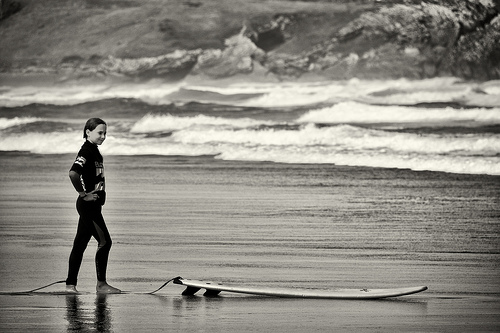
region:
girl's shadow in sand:
[36, 280, 138, 332]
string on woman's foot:
[5, 258, 72, 296]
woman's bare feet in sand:
[52, 275, 100, 297]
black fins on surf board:
[180, 281, 257, 296]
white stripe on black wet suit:
[60, 150, 96, 166]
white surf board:
[166, 265, 461, 310]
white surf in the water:
[300, 93, 405, 123]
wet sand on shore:
[162, 163, 327, 264]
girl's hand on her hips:
[58, 170, 124, 206]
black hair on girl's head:
[70, 109, 108, 144]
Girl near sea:
[49, 111, 142, 304]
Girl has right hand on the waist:
[59, 117, 138, 313]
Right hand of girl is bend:
[56, 109, 137, 311]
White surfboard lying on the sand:
[163, 261, 439, 309]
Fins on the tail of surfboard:
[176, 285, 222, 306]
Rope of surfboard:
[0, 265, 189, 302]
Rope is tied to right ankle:
[5, 269, 187, 308]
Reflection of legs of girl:
[53, 291, 128, 329]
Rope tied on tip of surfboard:
[139, 271, 182, 301]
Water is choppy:
[6, 11, 498, 141]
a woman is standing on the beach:
[50, 111, 125, 303]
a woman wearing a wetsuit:
[61, 116, 112, 294]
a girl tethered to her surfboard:
[6, 116, 187, 306]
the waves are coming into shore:
[0, 65, 495, 190]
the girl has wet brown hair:
[75, 115, 105, 141]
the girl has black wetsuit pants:
[65, 116, 121, 286]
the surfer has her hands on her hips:
[65, 117, 110, 283]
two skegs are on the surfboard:
[176, 271, 221, 301]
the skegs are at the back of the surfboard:
[170, 275, 228, 302]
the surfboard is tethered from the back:
[143, 272, 185, 301]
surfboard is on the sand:
[176, 265, 490, 312]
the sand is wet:
[196, 207, 331, 276]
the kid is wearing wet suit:
[62, 118, 152, 308]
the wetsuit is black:
[67, 151, 144, 307]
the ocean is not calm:
[163, 72, 454, 169]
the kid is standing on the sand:
[61, 108, 144, 320]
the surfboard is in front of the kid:
[157, 230, 435, 320]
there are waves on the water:
[138, 83, 413, 168]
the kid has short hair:
[56, 100, 112, 142]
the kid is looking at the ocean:
[73, 109, 382, 186]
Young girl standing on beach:
[64, 115, 121, 291]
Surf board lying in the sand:
[171, 273, 431, 302]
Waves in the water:
[214, 71, 366, 156]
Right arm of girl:
[68, 153, 101, 205]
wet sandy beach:
[139, 200, 261, 264]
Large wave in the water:
[340, 4, 478, 76]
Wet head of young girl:
[81, 115, 108, 146]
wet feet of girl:
[61, 279, 121, 294]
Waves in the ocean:
[309, 94, 394, 162]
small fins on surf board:
[181, 286, 219, 299]